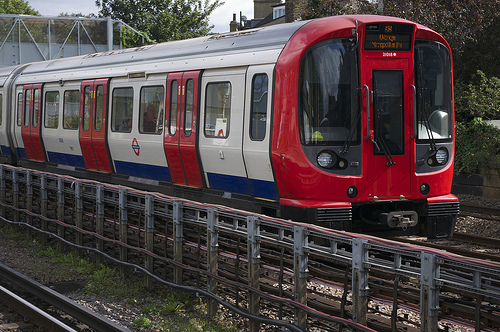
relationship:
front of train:
[276, 15, 460, 242] [6, 12, 464, 233]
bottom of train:
[0, 157, 460, 242] [6, 12, 464, 233]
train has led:
[6, 12, 464, 233] [362, 22, 414, 53]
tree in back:
[453, 1, 498, 116] [71, 1, 499, 36]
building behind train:
[252, 3, 333, 21] [6, 12, 464, 233]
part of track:
[462, 205, 480, 218] [385, 207, 499, 261]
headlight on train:
[313, 150, 348, 171] [6, 12, 464, 233]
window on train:
[111, 88, 132, 133] [6, 12, 464, 233]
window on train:
[203, 80, 231, 140] [6, 12, 464, 233]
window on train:
[43, 91, 61, 128] [6, 12, 464, 233]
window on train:
[247, 73, 268, 140] [6, 12, 464, 233]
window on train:
[302, 36, 357, 145] [6, 12, 464, 233]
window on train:
[413, 36, 454, 140] [6, 12, 464, 233]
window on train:
[138, 84, 163, 134] [6, 12, 464, 233]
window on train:
[64, 89, 80, 131] [6, 12, 464, 233]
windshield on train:
[373, 68, 405, 154] [6, 12, 464, 233]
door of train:
[160, 74, 210, 192] [6, 12, 464, 233]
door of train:
[364, 57, 411, 197] [6, 12, 464, 233]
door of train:
[78, 76, 114, 175] [6, 12, 464, 233]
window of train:
[43, 91, 61, 128] [6, 12, 464, 233]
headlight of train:
[427, 144, 450, 166] [6, 12, 464, 233]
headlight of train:
[313, 150, 348, 171] [6, 12, 464, 233]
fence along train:
[1, 163, 499, 331] [6, 12, 464, 233]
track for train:
[385, 207, 499, 261] [6, 12, 464, 233]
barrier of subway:
[0, 16, 119, 59] [0, 15, 457, 248]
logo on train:
[130, 138, 143, 156] [6, 12, 464, 233]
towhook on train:
[383, 211, 417, 230] [6, 12, 464, 233]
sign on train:
[362, 22, 414, 53] [6, 12, 464, 233]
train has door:
[6, 12, 464, 233] [160, 74, 210, 192]